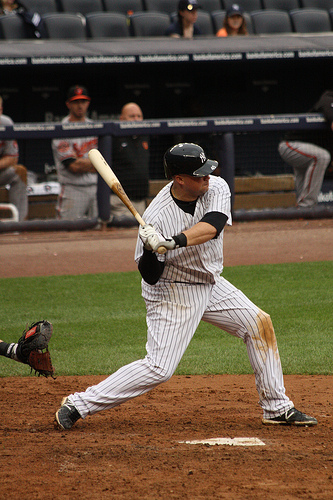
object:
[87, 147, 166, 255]
baseball bat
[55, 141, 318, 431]
man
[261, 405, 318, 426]
sneakers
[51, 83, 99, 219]
man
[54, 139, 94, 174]
arms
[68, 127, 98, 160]
chest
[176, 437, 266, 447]
home plate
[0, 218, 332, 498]
field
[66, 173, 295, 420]
uniform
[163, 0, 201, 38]
spectators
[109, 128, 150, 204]
shirt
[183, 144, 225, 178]
helmet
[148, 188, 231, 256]
arm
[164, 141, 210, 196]
head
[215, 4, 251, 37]
spectators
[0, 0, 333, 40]
bleachers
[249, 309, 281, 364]
dirt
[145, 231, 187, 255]
glove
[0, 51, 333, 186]
wall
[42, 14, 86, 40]
chair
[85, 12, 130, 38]
chair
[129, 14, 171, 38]
chair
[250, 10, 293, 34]
chair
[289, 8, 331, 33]
chair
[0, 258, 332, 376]
grass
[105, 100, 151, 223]
man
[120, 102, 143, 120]
head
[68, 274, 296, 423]
pants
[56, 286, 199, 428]
leg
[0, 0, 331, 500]
game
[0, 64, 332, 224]
dugout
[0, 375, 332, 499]
dirt